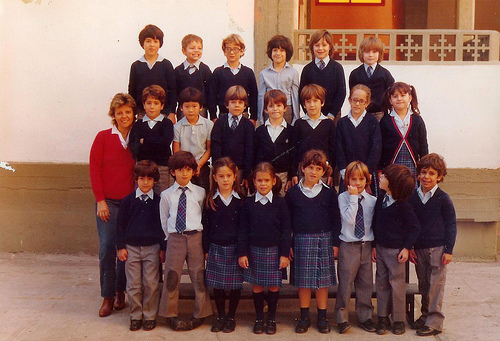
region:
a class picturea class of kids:
[90, 16, 478, 328]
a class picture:
[22, 3, 492, 333]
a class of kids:
[62, 21, 496, 317]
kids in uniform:
[65, 20, 482, 307]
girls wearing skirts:
[116, 23, 479, 325]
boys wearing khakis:
[35, 6, 499, 338]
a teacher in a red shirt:
[75, 53, 228, 339]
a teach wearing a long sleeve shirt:
[51, 70, 206, 340]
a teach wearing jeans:
[57, 99, 193, 327]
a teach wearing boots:
[52, 70, 202, 324]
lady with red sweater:
[80, 89, 133, 309]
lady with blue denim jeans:
[87, 94, 132, 316]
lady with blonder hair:
[88, 87, 135, 313]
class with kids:
[132, 30, 454, 335]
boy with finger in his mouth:
[340, 164, 380, 250]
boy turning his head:
[370, 153, 425, 336]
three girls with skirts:
[207, 146, 335, 331]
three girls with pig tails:
[205, 151, 335, 334]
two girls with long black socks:
[207, 152, 282, 337]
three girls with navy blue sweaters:
[210, 153, 348, 335]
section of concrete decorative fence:
[295, 28, 499, 63]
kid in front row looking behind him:
[371, 165, 421, 332]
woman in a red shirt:
[90, 93, 135, 317]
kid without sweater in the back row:
[256, 34, 298, 125]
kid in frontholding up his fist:
[338, 159, 377, 330]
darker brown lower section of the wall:
[1, 161, 498, 261]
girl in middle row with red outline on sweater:
[377, 81, 428, 173]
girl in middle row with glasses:
[341, 83, 380, 187]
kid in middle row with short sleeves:
[170, 86, 213, 188]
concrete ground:
[1, 250, 498, 337]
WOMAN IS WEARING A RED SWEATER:
[117, 166, 127, 178]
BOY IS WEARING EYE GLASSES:
[225, 48, 242, 53]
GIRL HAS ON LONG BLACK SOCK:
[270, 296, 275, 315]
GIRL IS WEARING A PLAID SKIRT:
[260, 256, 271, 278]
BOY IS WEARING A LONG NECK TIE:
[173, 194, 188, 231]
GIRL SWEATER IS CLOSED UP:
[398, 136, 413, 147]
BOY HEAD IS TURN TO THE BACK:
[372, 166, 408, 196]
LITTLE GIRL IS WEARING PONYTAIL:
[409, 92, 416, 110]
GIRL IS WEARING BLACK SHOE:
[252, 326, 269, 333]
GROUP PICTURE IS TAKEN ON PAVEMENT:
[97, 28, 444, 325]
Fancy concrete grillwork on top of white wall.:
[292, 27, 498, 64]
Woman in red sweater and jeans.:
[87, 91, 136, 316]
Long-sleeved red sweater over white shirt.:
[88, 125, 136, 204]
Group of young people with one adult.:
[88, 23, 457, 335]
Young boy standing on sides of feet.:
[158, 149, 214, 331]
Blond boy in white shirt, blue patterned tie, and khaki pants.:
[336, 157, 381, 334]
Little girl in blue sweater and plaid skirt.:
[237, 159, 289, 334]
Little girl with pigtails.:
[378, 80, 431, 187]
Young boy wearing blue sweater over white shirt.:
[408, 151, 458, 338]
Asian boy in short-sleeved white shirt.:
[172, 85, 215, 194]